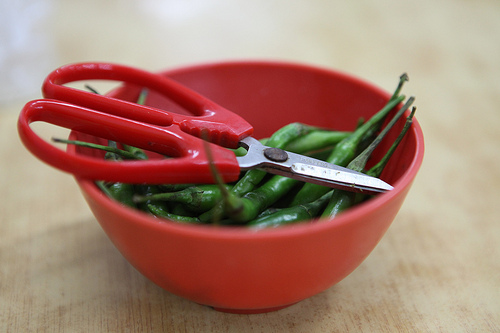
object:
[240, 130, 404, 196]
scissor blades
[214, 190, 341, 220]
food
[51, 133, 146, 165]
pepper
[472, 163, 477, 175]
ground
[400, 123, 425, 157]
ground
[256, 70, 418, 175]
beans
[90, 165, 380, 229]
beans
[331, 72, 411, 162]
green bean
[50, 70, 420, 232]
vegetables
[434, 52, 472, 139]
woodentable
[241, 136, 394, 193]
blades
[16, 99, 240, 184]
handle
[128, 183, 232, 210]
pepper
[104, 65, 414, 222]
green pepper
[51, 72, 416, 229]
green beans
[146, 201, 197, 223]
pepper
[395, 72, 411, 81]
bean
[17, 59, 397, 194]
kitchen shears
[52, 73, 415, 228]
beans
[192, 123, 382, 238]
pepper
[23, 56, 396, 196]
red scissors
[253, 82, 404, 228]
beans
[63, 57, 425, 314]
bowl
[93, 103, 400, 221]
beans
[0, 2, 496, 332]
table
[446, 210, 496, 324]
surface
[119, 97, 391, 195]
scissor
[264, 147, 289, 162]
screw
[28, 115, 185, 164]
hole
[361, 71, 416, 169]
edge